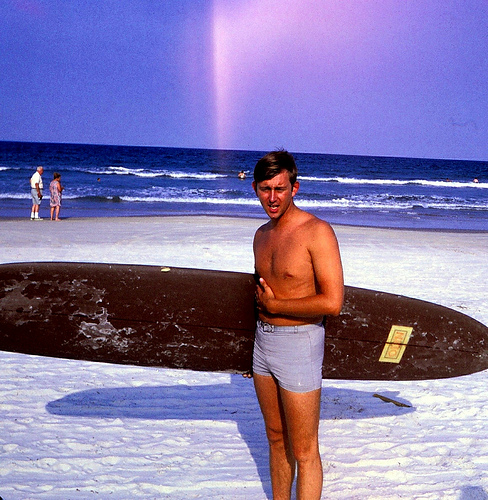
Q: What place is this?
A: It is a beach.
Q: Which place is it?
A: It is a beach.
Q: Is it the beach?
A: Yes, it is the beach.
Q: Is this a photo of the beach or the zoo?
A: It is showing the beach.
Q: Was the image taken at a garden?
A: No, the picture was taken in a beach.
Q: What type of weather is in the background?
A: It is clear.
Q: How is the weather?
A: It is clear.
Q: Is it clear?
A: Yes, it is clear.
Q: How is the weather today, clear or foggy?
A: It is clear.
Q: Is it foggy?
A: No, it is clear.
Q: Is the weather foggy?
A: No, it is clear.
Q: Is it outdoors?
A: Yes, it is outdoors.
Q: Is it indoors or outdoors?
A: It is outdoors.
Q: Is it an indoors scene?
A: No, it is outdoors.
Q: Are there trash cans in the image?
A: No, there are no trash cans.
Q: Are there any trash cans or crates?
A: No, there are no trash cans or crates.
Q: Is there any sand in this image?
A: Yes, there is sand.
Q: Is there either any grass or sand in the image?
A: Yes, there is sand.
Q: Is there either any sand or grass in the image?
A: Yes, there is sand.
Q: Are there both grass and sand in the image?
A: No, there is sand but no grass.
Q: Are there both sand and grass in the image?
A: No, there is sand but no grass.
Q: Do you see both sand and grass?
A: No, there is sand but no grass.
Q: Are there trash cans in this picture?
A: No, there are no trash cans.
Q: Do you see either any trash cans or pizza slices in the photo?
A: No, there are no trash cans or pizza slices.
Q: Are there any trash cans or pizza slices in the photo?
A: No, there are no trash cans or pizza slices.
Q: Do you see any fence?
A: No, there are no fences.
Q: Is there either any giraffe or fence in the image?
A: No, there are no fences or giraffes.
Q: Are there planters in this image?
A: No, there are no planters.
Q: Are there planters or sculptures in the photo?
A: No, there are no planters or sculptures.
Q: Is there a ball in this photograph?
A: No, there are no balls.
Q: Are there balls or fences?
A: No, there are no balls or fences.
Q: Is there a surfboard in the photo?
A: Yes, there is a surfboard.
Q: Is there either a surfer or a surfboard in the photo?
A: Yes, there is a surfboard.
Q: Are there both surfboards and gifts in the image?
A: No, there is a surfboard but no gifts.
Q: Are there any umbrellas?
A: No, there are no umbrellas.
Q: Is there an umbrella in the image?
A: No, there are no umbrellas.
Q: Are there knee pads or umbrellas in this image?
A: No, there are no umbrellas or knee pads.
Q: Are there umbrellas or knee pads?
A: No, there are no umbrellas or knee pads.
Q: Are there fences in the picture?
A: No, there are no fences.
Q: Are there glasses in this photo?
A: No, there are no glasses.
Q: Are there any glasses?
A: No, there are no glasses.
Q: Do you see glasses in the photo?
A: No, there are no glasses.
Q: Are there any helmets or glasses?
A: No, there are no glasses or helmets.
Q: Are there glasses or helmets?
A: No, there are no glasses or helmets.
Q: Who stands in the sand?
A: The man stands in the sand.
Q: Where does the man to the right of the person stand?
A: The man stands in the sand.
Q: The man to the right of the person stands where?
A: The man stands in the sand.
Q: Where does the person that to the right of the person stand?
A: The man stands in the sand.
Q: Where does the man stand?
A: The man stands in the sand.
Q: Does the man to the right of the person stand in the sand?
A: Yes, the man stands in the sand.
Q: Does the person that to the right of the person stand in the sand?
A: Yes, the man stands in the sand.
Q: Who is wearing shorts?
A: The man is wearing shorts.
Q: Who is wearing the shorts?
A: The man is wearing shorts.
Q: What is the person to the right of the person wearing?
A: The man is wearing shorts.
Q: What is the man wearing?
A: The man is wearing shorts.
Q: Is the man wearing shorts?
A: Yes, the man is wearing shorts.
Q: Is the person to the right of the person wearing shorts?
A: Yes, the man is wearing shorts.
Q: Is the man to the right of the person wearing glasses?
A: No, the man is wearing shorts.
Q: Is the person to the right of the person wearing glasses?
A: No, the man is wearing shorts.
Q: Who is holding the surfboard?
A: The man is holding the surfboard.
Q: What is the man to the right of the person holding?
A: The man is holding the surfboard.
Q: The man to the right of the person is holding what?
A: The man is holding the surfboard.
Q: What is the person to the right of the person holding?
A: The man is holding the surfboard.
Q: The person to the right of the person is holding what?
A: The man is holding the surfboard.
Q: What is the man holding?
A: The man is holding the surfboard.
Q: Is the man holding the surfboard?
A: Yes, the man is holding the surfboard.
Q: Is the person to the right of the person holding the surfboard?
A: Yes, the man is holding the surfboard.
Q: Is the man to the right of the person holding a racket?
A: No, the man is holding the surfboard.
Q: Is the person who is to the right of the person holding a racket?
A: No, the man is holding the surfboard.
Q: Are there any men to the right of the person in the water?
A: Yes, there is a man to the right of the person.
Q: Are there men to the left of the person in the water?
A: No, the man is to the right of the person.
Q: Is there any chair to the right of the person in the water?
A: No, there is a man to the right of the person.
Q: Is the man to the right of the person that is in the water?
A: Yes, the man is to the right of the person.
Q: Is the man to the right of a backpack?
A: No, the man is to the right of the person.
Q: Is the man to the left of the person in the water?
A: No, the man is to the right of the person.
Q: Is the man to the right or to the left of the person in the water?
A: The man is to the right of the person.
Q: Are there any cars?
A: No, there are no cars.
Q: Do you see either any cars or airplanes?
A: No, there are no cars or airplanes.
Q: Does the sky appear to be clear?
A: Yes, the sky is clear.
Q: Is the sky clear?
A: Yes, the sky is clear.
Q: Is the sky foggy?
A: No, the sky is clear.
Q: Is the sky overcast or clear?
A: The sky is clear.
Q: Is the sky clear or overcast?
A: The sky is clear.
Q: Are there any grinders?
A: No, there are no grinders.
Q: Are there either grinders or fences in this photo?
A: No, there are no grinders or fences.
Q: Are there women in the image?
A: Yes, there is a woman.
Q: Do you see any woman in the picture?
A: Yes, there is a woman.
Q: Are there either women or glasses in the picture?
A: Yes, there is a woman.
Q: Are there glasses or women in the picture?
A: Yes, there is a woman.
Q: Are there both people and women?
A: Yes, there are both a woman and a person.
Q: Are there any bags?
A: No, there are no bags.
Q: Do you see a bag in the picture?
A: No, there are no bags.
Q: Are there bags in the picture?
A: No, there are no bags.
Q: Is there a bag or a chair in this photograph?
A: No, there are no bags or chairs.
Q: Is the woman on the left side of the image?
A: Yes, the woman is on the left of the image.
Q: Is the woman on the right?
A: No, the woman is on the left of the image.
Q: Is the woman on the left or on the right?
A: The woman is on the left of the image.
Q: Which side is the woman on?
A: The woman is on the left of the image.